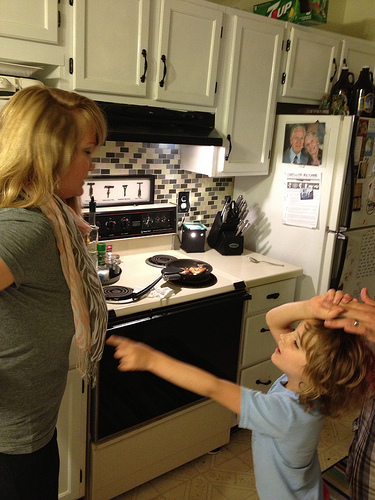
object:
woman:
[0, 85, 109, 499]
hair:
[0, 85, 106, 211]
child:
[106, 289, 374, 500]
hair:
[298, 316, 374, 420]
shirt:
[237, 372, 324, 498]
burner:
[103, 285, 134, 300]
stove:
[77, 231, 245, 323]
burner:
[145, 252, 177, 268]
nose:
[88, 155, 94, 171]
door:
[90, 289, 245, 444]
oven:
[82, 202, 177, 252]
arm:
[151, 348, 288, 428]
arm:
[266, 289, 313, 348]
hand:
[321, 287, 374, 346]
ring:
[353, 318, 358, 327]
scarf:
[40, 191, 108, 385]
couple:
[282, 123, 326, 166]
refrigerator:
[232, 111, 374, 301]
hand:
[309, 289, 358, 321]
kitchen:
[1, 0, 374, 497]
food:
[189, 267, 206, 275]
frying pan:
[165, 259, 213, 284]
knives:
[221, 194, 251, 236]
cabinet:
[180, 6, 287, 178]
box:
[250, 0, 331, 27]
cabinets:
[339, 34, 374, 84]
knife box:
[206, 211, 244, 257]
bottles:
[327, 64, 355, 116]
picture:
[80, 174, 155, 209]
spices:
[96, 240, 107, 265]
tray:
[96, 262, 123, 285]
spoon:
[249, 257, 285, 267]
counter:
[215, 241, 304, 290]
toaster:
[180, 221, 208, 253]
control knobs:
[106, 221, 115, 231]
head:
[270, 313, 362, 387]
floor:
[112, 455, 251, 498]